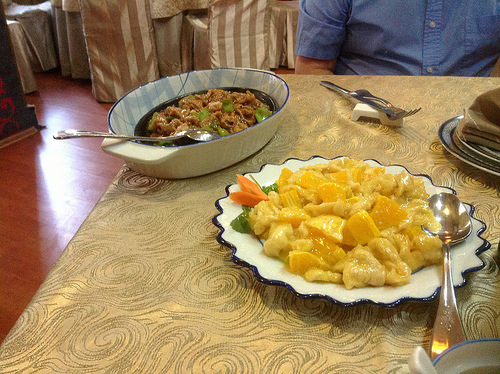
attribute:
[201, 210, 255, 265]
dish — white, food, beef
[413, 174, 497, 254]
spoon — silver, metal, giant, white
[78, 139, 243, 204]
bowl — white, stew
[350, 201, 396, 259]
potato — salad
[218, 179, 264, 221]
carrot — slice, orange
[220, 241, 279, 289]
plate — pasta, ridge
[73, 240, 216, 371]
cloth — table, covered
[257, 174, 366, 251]
pasta — garnish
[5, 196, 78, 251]
floor — hardwood, wood, reflection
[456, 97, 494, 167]
napkin — stack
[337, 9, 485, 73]
shirt — blue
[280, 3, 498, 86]
person — sitting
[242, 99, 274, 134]
bell — green